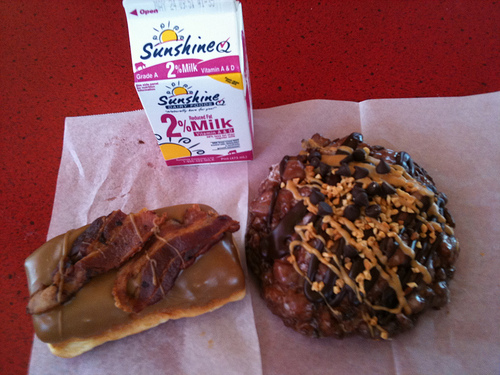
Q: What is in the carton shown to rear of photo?
A: Milk.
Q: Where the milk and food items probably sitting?
A: Table.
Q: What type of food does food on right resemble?
A: Cookie.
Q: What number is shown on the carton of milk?
A: 2.